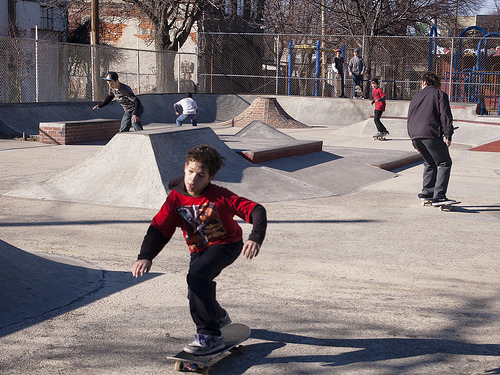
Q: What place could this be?
A: It is a park.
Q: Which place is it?
A: It is a park.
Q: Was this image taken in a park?
A: Yes, it was taken in a park.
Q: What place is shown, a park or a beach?
A: It is a park.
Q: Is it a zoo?
A: No, it is a park.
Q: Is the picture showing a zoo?
A: No, the picture is showing a park.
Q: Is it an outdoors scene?
A: Yes, it is outdoors.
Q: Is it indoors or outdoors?
A: It is outdoors.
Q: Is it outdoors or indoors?
A: It is outdoors.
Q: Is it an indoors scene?
A: No, it is outdoors.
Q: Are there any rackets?
A: No, there are no rackets.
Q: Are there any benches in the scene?
A: Yes, there is a bench.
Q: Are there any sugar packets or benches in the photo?
A: Yes, there is a bench.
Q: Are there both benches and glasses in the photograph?
A: No, there is a bench but no glasses.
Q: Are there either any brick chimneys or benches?
A: Yes, there is a brick bench.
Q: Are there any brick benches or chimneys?
A: Yes, there is a brick bench.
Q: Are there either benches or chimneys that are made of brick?
A: Yes, the bench is made of brick.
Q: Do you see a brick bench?
A: Yes, there is a bench that is made of brick.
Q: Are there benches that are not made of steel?
A: Yes, there is a bench that is made of brick.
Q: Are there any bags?
A: No, there are no bags.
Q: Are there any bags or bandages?
A: No, there are no bags or bandages.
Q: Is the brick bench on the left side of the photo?
A: Yes, the bench is on the left of the image.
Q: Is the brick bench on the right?
A: No, the bench is on the left of the image.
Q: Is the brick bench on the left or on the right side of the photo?
A: The bench is on the left of the image.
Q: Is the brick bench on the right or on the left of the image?
A: The bench is on the left of the image.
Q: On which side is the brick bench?
A: The bench is on the left of the image.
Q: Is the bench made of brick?
A: Yes, the bench is made of brick.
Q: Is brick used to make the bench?
A: Yes, the bench is made of brick.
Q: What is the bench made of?
A: The bench is made of brick.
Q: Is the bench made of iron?
A: No, the bench is made of brick.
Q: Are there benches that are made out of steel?
A: No, there is a bench but it is made of brick.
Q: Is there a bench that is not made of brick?
A: No, there is a bench but it is made of brick.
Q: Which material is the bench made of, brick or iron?
A: The bench is made of brick.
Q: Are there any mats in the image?
A: No, there are no mats.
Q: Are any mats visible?
A: No, there are no mats.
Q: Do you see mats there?
A: No, there are no mats.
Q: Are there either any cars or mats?
A: No, there are no mats or cars.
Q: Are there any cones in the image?
A: No, there are no cones.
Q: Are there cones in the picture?
A: No, there are no cones.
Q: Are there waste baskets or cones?
A: No, there are no cones or waste baskets.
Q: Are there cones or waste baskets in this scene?
A: No, there are no cones or waste baskets.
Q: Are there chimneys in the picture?
A: No, there are no chimneys.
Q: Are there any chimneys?
A: No, there are no chimneys.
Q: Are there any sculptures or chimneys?
A: No, there are no chimneys or sculptures.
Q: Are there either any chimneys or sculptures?
A: No, there are no chimneys or sculptures.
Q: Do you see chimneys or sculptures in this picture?
A: No, there are no chimneys or sculptures.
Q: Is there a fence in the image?
A: Yes, there is a fence.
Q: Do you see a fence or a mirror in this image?
A: Yes, there is a fence.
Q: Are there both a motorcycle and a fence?
A: No, there is a fence but no motorcycles.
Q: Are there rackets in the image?
A: No, there are no rackets.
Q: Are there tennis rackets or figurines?
A: No, there are no tennis rackets or figurines.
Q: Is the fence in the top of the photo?
A: Yes, the fence is in the top of the image.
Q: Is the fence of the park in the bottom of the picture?
A: No, the fence is in the top of the image.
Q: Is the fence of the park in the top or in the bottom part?
A: The fence is in the top of the image.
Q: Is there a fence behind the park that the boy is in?
A: Yes, there is a fence behind the park.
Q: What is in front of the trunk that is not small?
A: The fence is in front of the trunk.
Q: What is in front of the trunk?
A: The fence is in front of the trunk.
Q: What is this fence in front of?
A: The fence is in front of the trunk.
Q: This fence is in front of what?
A: The fence is in front of the trunk.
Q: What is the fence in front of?
A: The fence is in front of the trunk.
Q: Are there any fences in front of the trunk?
A: Yes, there is a fence in front of the trunk.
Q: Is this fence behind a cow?
A: No, the fence is behind a boy.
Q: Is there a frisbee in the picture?
A: No, there are no frisbees.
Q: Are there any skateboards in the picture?
A: Yes, there is a skateboard.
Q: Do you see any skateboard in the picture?
A: Yes, there is a skateboard.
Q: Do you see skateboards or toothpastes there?
A: Yes, there is a skateboard.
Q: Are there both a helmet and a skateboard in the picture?
A: No, there is a skateboard but no helmets.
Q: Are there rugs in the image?
A: No, there are no rugs.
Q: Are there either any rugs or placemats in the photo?
A: No, there are no rugs or placemats.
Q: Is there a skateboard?
A: Yes, there is a skateboard.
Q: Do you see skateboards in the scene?
A: Yes, there is a skateboard.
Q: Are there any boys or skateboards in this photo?
A: Yes, there is a skateboard.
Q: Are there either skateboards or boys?
A: Yes, there is a skateboard.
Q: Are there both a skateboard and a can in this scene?
A: No, there is a skateboard but no cans.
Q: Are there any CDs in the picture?
A: No, there are no cds.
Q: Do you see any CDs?
A: No, there are no cds.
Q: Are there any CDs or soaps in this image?
A: No, there are no CDs or soaps.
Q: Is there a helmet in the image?
A: No, there are no helmets.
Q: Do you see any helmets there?
A: No, there are no helmets.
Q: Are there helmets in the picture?
A: No, there are no helmets.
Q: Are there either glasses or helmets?
A: No, there are no helmets or glasses.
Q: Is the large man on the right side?
A: Yes, the man is on the right of the image.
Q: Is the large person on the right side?
A: Yes, the man is on the right of the image.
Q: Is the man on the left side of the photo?
A: No, the man is on the right of the image.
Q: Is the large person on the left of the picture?
A: No, the man is on the right of the image.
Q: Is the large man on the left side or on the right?
A: The man is on the right of the image.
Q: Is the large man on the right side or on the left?
A: The man is on the right of the image.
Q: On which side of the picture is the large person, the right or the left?
A: The man is on the right of the image.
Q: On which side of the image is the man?
A: The man is on the right of the image.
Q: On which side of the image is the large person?
A: The man is on the right of the image.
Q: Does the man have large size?
A: Yes, the man is large.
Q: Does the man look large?
A: Yes, the man is large.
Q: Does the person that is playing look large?
A: Yes, the man is large.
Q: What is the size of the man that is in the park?
A: The man is large.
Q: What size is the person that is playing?
A: The man is large.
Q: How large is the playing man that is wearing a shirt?
A: The man is large.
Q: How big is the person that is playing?
A: The man is large.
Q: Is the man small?
A: No, the man is large.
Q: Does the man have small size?
A: No, the man is large.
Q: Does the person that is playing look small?
A: No, the man is large.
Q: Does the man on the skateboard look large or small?
A: The man is large.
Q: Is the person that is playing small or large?
A: The man is large.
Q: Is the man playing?
A: Yes, the man is playing.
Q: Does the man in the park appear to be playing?
A: Yes, the man is playing.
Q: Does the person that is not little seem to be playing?
A: Yes, the man is playing.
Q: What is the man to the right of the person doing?
A: The man is playing.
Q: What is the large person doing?
A: The man is playing.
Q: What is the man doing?
A: The man is playing.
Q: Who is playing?
A: The man is playing.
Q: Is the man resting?
A: No, the man is playing.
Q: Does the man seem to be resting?
A: No, the man is playing.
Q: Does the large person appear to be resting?
A: No, the man is playing.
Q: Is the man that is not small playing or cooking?
A: The man is playing.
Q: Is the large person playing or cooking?
A: The man is playing.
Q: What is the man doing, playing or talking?
A: The man is playing.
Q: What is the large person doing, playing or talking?
A: The man is playing.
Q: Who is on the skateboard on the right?
A: The man is on the skateboard.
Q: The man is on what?
A: The man is on the skateboard.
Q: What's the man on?
A: The man is on the skateboard.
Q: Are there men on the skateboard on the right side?
A: Yes, there is a man on the skateboard.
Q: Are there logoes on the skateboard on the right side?
A: No, there is a man on the skateboard.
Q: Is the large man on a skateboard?
A: Yes, the man is on a skateboard.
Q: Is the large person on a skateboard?
A: Yes, the man is on a skateboard.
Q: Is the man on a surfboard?
A: No, the man is on a skateboard.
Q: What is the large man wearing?
A: The man is wearing a shirt.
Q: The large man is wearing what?
A: The man is wearing a shirt.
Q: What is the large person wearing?
A: The man is wearing a shirt.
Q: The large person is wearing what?
A: The man is wearing a shirt.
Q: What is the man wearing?
A: The man is wearing a shirt.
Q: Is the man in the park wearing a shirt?
A: Yes, the man is wearing a shirt.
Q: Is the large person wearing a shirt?
A: Yes, the man is wearing a shirt.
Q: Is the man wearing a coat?
A: No, the man is wearing a shirt.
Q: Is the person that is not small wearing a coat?
A: No, the man is wearing a shirt.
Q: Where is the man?
A: The man is in the park.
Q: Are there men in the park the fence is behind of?
A: Yes, there is a man in the park.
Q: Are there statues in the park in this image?
A: No, there is a man in the park.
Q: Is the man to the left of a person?
A: No, the man is to the right of a person.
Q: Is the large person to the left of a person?
A: No, the man is to the right of a person.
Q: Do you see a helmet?
A: No, there are no helmets.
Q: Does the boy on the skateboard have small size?
A: Yes, the boy is small.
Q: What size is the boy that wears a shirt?
A: The boy is small.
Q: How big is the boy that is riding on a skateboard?
A: The boy is small.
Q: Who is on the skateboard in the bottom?
A: The boy is on the skateboard.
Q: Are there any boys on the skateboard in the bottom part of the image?
A: Yes, there is a boy on the skateboard.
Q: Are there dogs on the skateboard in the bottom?
A: No, there is a boy on the skateboard.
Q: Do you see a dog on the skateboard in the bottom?
A: No, there is a boy on the skateboard.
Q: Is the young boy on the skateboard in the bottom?
A: Yes, the boy is on the skateboard.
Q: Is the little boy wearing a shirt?
A: Yes, the boy is wearing a shirt.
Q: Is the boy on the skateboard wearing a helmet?
A: No, the boy is wearing a shirt.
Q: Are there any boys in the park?
A: Yes, there is a boy in the park.